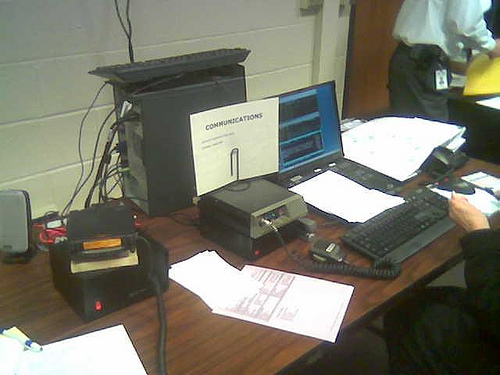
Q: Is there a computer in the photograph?
A: Yes, there is a computer.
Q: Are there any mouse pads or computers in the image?
A: Yes, there is a computer.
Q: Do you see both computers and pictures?
A: No, there is a computer but no pictures.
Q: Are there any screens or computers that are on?
A: Yes, the computer is on.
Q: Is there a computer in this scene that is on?
A: Yes, there is a computer that is on.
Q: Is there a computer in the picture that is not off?
A: Yes, there is a computer that is on.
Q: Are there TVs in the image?
A: No, there are no tvs.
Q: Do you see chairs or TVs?
A: No, there are no TVs or chairs.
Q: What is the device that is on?
A: The device is a computer.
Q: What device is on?
A: The device is a computer.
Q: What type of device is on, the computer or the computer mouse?
A: The computer is on.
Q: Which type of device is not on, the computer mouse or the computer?
A: The computer mouse is not on.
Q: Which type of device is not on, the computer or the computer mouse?
A: The computer mouse is not on.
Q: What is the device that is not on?
A: The device is a computer mouse.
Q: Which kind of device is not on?
A: The device is a computer mouse.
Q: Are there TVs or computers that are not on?
A: No, there is a computer but it is on.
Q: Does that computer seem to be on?
A: Yes, the computer is on.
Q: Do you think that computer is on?
A: Yes, the computer is on.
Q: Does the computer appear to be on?
A: Yes, the computer is on.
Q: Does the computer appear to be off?
A: No, the computer is on.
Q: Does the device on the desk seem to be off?
A: No, the computer is on.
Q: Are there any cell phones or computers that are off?
A: No, there is a computer but it is on.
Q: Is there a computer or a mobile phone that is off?
A: No, there is a computer but it is on.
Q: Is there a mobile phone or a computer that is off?
A: No, there is a computer but it is on.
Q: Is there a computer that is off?
A: No, there is a computer but it is on.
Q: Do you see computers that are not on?
A: No, there is a computer but it is on.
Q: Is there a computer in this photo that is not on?
A: No, there is a computer but it is on.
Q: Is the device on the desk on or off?
A: The computer is on.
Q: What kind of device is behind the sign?
A: The device is a computer.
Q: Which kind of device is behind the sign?
A: The device is a computer.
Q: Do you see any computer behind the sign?
A: Yes, there is a computer behind the sign.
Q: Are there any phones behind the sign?
A: No, there is a computer behind the sign.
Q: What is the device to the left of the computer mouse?
A: The device is a computer.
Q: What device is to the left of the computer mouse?
A: The device is a computer.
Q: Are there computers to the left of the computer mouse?
A: Yes, there is a computer to the left of the computer mouse.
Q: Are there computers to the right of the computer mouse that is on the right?
A: No, the computer is to the left of the mouse.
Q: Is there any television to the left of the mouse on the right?
A: No, there is a computer to the left of the mouse.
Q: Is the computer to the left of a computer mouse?
A: Yes, the computer is to the left of a computer mouse.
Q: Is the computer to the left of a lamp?
A: No, the computer is to the left of a computer mouse.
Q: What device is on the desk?
A: The device is a computer.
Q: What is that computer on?
A: The computer is on the desk.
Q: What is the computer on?
A: The computer is on the desk.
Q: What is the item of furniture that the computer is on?
A: The piece of furniture is a desk.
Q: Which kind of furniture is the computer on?
A: The computer is on the desk.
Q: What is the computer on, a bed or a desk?
A: The computer is on a desk.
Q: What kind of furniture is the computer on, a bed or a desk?
A: The computer is on a desk.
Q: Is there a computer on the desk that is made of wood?
A: Yes, there is a computer on the desk.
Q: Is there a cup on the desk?
A: No, there is a computer on the desk.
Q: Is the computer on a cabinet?
A: No, the computer is on the desk.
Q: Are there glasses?
A: No, there are no glasses.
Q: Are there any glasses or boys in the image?
A: No, there are no glasses or boys.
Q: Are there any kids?
A: No, there are no kids.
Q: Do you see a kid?
A: No, there are no children.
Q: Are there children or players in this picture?
A: No, there are no children or players.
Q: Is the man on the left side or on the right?
A: The man is on the right of the image.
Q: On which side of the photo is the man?
A: The man is on the right of the image.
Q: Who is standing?
A: The man is standing.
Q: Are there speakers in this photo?
A: Yes, there is a speaker.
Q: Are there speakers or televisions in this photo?
A: Yes, there is a speaker.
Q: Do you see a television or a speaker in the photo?
A: Yes, there is a speaker.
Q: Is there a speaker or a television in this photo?
A: Yes, there is a speaker.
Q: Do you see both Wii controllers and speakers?
A: No, there is a speaker but no Wii controllers.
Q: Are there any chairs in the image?
A: No, there are no chairs.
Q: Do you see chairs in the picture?
A: No, there are no chairs.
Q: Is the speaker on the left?
A: Yes, the speaker is on the left of the image.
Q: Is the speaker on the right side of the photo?
A: No, the speaker is on the left of the image.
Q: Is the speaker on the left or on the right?
A: The speaker is on the left of the image.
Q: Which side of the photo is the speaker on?
A: The speaker is on the left of the image.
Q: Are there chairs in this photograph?
A: No, there are no chairs.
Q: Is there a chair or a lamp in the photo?
A: No, there are no chairs or lamps.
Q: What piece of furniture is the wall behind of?
A: The wall is behind the desk.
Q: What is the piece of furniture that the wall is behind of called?
A: The piece of furniture is a desk.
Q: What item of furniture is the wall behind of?
A: The wall is behind the desk.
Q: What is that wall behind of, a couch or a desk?
A: The wall is behind a desk.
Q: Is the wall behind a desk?
A: Yes, the wall is behind a desk.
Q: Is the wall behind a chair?
A: No, the wall is behind a desk.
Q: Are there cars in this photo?
A: No, there are no cars.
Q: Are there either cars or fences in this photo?
A: No, there are no cars or fences.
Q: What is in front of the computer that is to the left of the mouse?
A: The sign is in front of the computer.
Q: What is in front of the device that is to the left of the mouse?
A: The sign is in front of the computer.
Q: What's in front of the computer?
A: The sign is in front of the computer.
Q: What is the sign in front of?
A: The sign is in front of the computer.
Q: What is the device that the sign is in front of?
A: The device is a computer.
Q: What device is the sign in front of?
A: The sign is in front of the computer.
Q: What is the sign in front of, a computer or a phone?
A: The sign is in front of a computer.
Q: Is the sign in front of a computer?
A: Yes, the sign is in front of a computer.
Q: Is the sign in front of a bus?
A: No, the sign is in front of a computer.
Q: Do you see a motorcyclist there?
A: No, there are no bikers.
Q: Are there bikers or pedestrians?
A: No, there are no bikers or pedestrians.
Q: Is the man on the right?
A: Yes, the man is on the right of the image.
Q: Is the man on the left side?
A: No, the man is on the right of the image.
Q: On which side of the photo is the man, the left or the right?
A: The man is on the right of the image.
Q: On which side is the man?
A: The man is on the right of the image.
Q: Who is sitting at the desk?
A: The man is sitting at the desk.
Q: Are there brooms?
A: No, there are no brooms.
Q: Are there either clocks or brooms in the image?
A: No, there are no brooms or clocks.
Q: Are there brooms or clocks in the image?
A: No, there are no brooms or clocks.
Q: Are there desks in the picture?
A: Yes, there is a desk.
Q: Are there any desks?
A: Yes, there is a desk.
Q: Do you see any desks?
A: Yes, there is a desk.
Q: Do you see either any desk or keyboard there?
A: Yes, there is a desk.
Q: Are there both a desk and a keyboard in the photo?
A: Yes, there are both a desk and a keyboard.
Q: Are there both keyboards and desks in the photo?
A: Yes, there are both a desk and a keyboard.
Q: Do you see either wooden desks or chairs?
A: Yes, there is a wood desk.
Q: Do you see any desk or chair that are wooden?
A: Yes, the desk is wooden.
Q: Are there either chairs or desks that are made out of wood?
A: Yes, the desk is made of wood.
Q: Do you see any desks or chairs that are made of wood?
A: Yes, the desk is made of wood.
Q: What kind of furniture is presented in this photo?
A: The furniture is a desk.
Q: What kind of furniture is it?
A: The piece of furniture is a desk.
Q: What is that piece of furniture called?
A: This is a desk.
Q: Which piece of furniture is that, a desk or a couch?
A: This is a desk.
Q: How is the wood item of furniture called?
A: The piece of furniture is a desk.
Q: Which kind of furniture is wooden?
A: The furniture is a desk.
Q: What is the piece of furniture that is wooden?
A: The piece of furniture is a desk.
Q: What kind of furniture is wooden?
A: The furniture is a desk.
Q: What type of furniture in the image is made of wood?
A: The furniture is a desk.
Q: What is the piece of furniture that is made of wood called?
A: The piece of furniture is a desk.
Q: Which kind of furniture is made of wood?
A: The furniture is a desk.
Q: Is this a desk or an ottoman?
A: This is a desk.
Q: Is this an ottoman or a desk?
A: This is a desk.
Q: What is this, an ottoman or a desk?
A: This is a desk.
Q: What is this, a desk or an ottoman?
A: This is a desk.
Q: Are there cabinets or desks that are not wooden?
A: No, there is a desk but it is wooden.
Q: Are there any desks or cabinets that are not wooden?
A: No, there is a desk but it is wooden.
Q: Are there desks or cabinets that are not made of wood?
A: No, there is a desk but it is made of wood.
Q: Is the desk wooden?
A: Yes, the desk is wooden.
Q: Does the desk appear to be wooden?
A: Yes, the desk is wooden.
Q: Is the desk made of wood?
A: Yes, the desk is made of wood.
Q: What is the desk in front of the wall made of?
A: The desk is made of wood.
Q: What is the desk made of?
A: The desk is made of wood.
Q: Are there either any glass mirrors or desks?
A: No, there is a desk but it is wooden.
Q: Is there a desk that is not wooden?
A: No, there is a desk but it is wooden.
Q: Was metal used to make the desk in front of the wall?
A: No, the desk is made of wood.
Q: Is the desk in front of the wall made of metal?
A: No, the desk is made of wood.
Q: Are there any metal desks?
A: No, there is a desk but it is made of wood.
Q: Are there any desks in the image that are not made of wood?
A: No, there is a desk but it is made of wood.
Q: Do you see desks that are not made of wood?
A: No, there is a desk but it is made of wood.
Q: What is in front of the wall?
A: The desk is in front of the wall.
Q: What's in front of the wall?
A: The desk is in front of the wall.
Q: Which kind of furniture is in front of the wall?
A: The piece of furniture is a desk.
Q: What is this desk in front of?
A: The desk is in front of the wall.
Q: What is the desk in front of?
A: The desk is in front of the wall.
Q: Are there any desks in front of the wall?
A: Yes, there is a desk in front of the wall.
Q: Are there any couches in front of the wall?
A: No, there is a desk in front of the wall.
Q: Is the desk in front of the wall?
A: Yes, the desk is in front of the wall.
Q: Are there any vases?
A: No, there are no vases.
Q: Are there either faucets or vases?
A: No, there are no vases or faucets.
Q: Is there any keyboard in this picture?
A: Yes, there is a keyboard.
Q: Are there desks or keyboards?
A: Yes, there is a keyboard.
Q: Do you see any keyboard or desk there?
A: Yes, there is a keyboard.